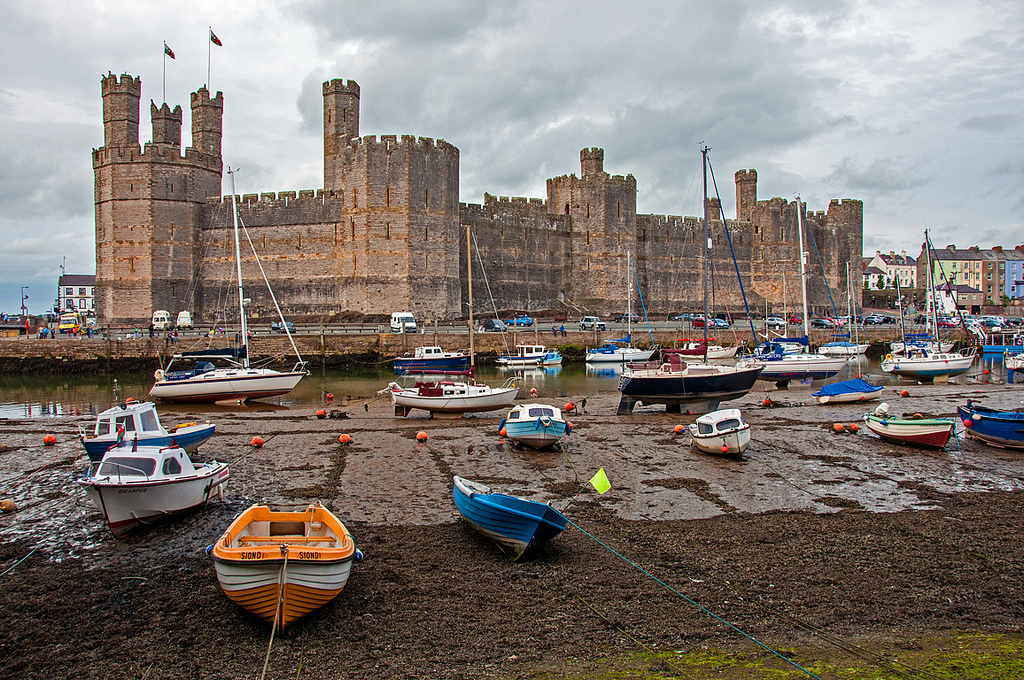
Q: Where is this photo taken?
A: Boating dock.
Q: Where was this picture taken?
A: Close to boats.